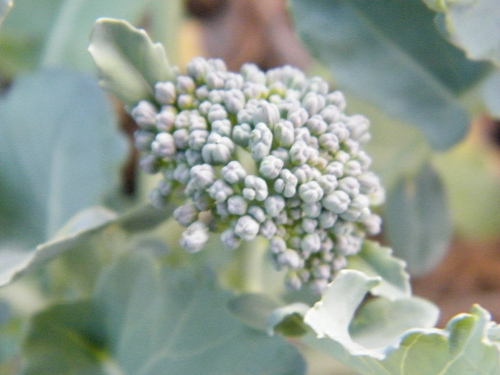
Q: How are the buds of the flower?
A: Closed.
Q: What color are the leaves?
A: Green.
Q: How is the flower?
A: It has not bloomed.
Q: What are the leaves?
A: Curved.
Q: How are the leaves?
A: Succulent.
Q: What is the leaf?
A: Veined.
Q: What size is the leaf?
A: Small.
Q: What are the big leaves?
A: Broccoli.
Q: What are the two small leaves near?
A: Florets.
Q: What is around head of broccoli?
A: Big leaves.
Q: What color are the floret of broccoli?
A: Green.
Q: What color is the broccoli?
A: Green.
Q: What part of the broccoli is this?
A: Floret.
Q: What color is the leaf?
A: Green.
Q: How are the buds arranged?
A: In a bunch.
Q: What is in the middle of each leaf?
A: Veins.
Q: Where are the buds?
A: On the plant.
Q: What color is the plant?
A: Green.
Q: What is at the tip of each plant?
A: Buds.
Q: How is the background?
A: Blurry.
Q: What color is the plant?
A: White.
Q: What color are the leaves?
A: Green.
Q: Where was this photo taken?
A: In a garden.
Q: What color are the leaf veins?
A: White.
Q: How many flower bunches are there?
A: One.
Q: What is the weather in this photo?
A: Sunshine.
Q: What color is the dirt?
A: Brown.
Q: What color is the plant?
A: Green.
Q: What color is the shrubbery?
A: Green.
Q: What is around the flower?
A: Leaves.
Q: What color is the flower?
A: White.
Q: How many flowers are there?
A: One.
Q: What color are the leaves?
A: Green.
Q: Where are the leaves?
A: Around the flower.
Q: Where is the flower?
A: Next to the leaves.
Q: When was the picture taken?
A: Daytime.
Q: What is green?
A: The leaves.